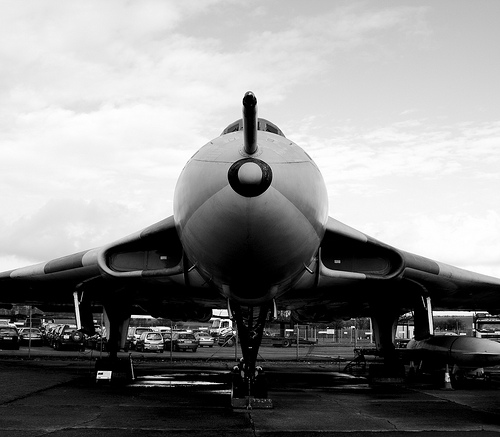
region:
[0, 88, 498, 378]
this is a plane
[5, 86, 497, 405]
the plane is big in size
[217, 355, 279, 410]
the wheels are on the ground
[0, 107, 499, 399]
the plane is white in color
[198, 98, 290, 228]
the plane has sharp head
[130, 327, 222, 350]
cars are parked behind the plane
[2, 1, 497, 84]
the sky is grey in color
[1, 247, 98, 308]
this is the planes wing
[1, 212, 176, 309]
the wing is slanted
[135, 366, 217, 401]
the floor is wet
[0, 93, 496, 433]
Front view of the airplaine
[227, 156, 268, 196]
Nose of the airplane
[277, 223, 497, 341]
Front view of the left arm of the airplane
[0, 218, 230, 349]
Front view of the right arm of the airplane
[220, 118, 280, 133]
Windows of the airplane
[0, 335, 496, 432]
Part of the docking station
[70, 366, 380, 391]
Landing point for the airplane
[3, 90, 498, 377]
The airplane is currently at rest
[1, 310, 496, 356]
parking lot for vehicles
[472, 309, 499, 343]
Front view of school bus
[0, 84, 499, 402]
large airplane at the airport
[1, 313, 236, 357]
cars parked in a parking lot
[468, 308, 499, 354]
large truck at the airport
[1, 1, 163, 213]
large cumulus clouds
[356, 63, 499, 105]
a clear section of sky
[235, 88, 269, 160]
the front tip of an airplane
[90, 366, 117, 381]
a block keeping an airplane wheel in place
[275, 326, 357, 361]
metal chain link fence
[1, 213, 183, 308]
wing of an airplane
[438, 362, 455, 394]
a cone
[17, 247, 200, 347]
wing of a plane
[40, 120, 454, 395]
plane in black and white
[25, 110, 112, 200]
sky in black and white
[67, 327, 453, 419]
plane landing gear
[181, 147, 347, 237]
the nose of a plane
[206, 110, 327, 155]
cockpit area of plane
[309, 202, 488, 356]
right wing of plane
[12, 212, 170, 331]
left wing of plane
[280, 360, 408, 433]
plane parking area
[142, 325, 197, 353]
cars in the background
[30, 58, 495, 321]
Plane on the tarmac.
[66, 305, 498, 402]
Wheels on the plane.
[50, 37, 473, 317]
Sky behind the plane.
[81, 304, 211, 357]
Car behind the plane.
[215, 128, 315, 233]
Propeller on the plane.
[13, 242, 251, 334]
Wings on the plane.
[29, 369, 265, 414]
Water under the plane.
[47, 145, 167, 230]
Clouds in the sky.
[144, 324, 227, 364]
Fence in front of the car.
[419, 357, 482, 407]
Cone on the tarmac.